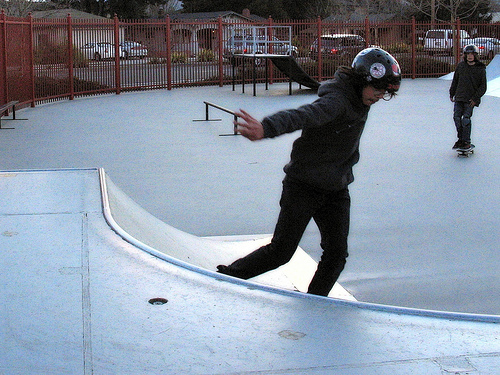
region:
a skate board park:
[180, 53, 440, 321]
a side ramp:
[91, 173, 441, 344]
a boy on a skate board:
[425, 29, 479, 160]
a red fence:
[20, 12, 185, 88]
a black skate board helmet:
[347, 43, 405, 126]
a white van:
[415, 23, 470, 49]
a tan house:
[41, 9, 128, 74]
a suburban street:
[20, 11, 463, 85]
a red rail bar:
[194, 86, 252, 163]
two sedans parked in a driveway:
[80, 36, 167, 75]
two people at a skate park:
[104, 6, 498, 369]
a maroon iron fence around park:
[4, 4, 499, 94]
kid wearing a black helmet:
[334, 31, 408, 108]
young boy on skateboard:
[438, 42, 491, 177]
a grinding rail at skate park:
[190, 87, 251, 145]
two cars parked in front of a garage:
[66, 29, 154, 71]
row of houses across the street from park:
[12, 5, 446, 66]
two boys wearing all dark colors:
[227, 38, 494, 297]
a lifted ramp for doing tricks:
[229, 20, 360, 101]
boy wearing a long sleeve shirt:
[445, 41, 493, 109]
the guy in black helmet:
[242, 4, 429, 190]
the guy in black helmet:
[307, 69, 376, 140]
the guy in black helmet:
[297, 30, 436, 245]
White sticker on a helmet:
[368, 62, 387, 77]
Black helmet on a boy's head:
[347, 50, 407, 87]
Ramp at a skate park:
[95, 162, 347, 301]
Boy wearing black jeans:
[448, 101, 477, 148]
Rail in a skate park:
[191, 98, 256, 134]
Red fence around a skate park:
[66, 26, 130, 96]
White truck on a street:
[422, 26, 473, 55]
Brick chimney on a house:
[237, 7, 256, 17]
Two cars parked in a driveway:
[83, 40, 159, 59]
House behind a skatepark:
[132, 11, 293, 62]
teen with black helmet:
[339, 38, 411, 112]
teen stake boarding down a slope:
[202, 39, 487, 345]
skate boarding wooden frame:
[221, 42, 336, 92]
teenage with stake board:
[448, 39, 490, 161]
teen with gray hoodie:
[259, 57, 398, 194]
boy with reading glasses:
[339, 75, 403, 113]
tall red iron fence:
[46, 10, 193, 100]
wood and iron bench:
[1, 97, 28, 129]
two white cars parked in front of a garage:
[44, 9, 161, 71]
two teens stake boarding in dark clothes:
[206, 30, 498, 292]